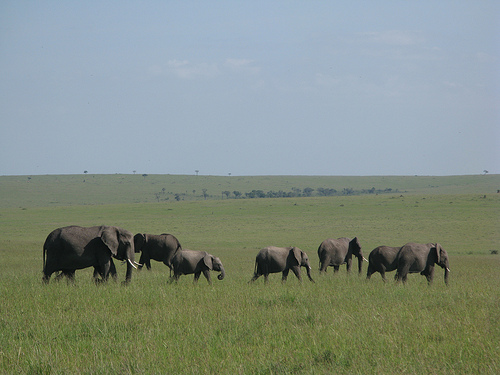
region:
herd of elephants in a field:
[35, 217, 455, 291]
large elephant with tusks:
[36, 222, 136, 287]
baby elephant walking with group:
[166, 245, 224, 287]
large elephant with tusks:
[396, 242, 453, 286]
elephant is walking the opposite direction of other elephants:
[129, 228, 181, 273]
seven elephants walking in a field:
[36, 223, 448, 285]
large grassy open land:
[0, 172, 499, 374]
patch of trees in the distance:
[198, 184, 403, 196]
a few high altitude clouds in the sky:
[121, 22, 426, 83]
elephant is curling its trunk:
[168, 252, 223, 284]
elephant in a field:
[36, 217, 134, 285]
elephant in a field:
[125, 222, 175, 272]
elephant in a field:
[170, 246, 232, 284]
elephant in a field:
[248, 243, 317, 285]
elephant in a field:
[316, 221, 362, 271]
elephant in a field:
[367, 238, 399, 284]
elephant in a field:
[398, 241, 452, 286]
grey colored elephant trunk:
[121, 251, 136, 287]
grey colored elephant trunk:
[216, 265, 226, 280]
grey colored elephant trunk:
[304, 267, 319, 282]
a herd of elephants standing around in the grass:
[41, 221, 452, 288]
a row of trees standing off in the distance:
[218, 183, 398, 201]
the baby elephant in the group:
[178, 248, 225, 285]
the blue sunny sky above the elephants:
[2, 3, 499, 171]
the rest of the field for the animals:
[4, 176, 496, 278]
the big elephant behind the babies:
[44, 223, 136, 285]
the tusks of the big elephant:
[126, 256, 141, 269]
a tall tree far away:
[191, 168, 201, 180]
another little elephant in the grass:
[248, 243, 316, 285]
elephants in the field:
[2, 186, 441, 294]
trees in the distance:
[165, 178, 372, 200]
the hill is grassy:
[11, 170, 113, 195]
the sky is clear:
[114, 119, 273, 160]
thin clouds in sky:
[125, 44, 299, 87]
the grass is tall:
[142, 311, 258, 357]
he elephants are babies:
[236, 219, 451, 292]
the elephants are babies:
[128, 231, 223, 286]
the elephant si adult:
[37, 208, 146, 285]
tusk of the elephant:
[122, 259, 142, 267]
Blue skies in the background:
[130, 79, 232, 147]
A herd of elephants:
[17, 208, 458, 328]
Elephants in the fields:
[20, 206, 476, 306]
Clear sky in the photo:
[137, 46, 324, 112]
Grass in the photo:
[134, 285, 280, 351]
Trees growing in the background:
[155, 184, 385, 203]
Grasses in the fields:
[185, 298, 297, 347]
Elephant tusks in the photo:
[123, 258, 141, 270]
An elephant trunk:
[215, 263, 227, 280]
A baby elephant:
[168, 252, 238, 291]